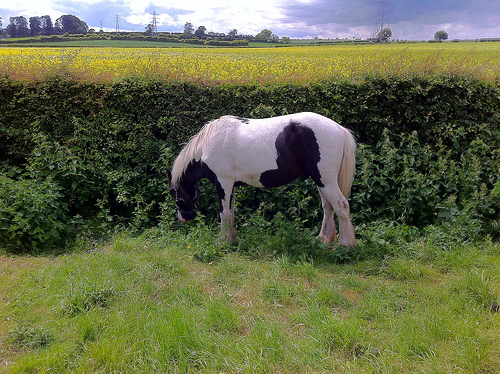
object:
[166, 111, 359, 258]
horse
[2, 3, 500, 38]
sky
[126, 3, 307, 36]
cloud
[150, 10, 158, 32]
power pole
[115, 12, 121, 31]
power pole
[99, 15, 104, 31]
power pole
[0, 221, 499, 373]
grass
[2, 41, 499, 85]
field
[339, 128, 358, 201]
tail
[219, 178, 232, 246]
front leg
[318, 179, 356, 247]
back leg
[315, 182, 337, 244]
back leg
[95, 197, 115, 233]
plant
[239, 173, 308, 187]
stomach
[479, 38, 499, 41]
train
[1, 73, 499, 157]
bush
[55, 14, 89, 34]
tree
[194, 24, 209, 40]
tree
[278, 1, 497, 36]
cloud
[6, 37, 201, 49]
ground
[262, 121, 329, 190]
spot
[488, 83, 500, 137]
edge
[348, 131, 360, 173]
edge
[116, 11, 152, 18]
power line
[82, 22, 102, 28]
power line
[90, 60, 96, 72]
flower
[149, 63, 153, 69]
flower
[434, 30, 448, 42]
tree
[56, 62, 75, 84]
weed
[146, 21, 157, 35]
tree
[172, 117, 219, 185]
mane